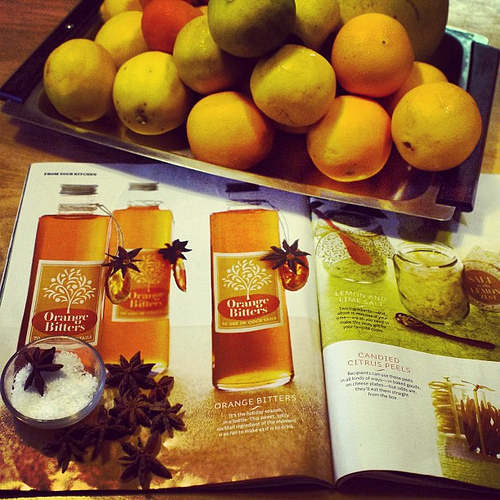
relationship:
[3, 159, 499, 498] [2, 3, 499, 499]
magazine on table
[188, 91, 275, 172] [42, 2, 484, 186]
orange in pile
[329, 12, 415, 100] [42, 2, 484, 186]
orange in pile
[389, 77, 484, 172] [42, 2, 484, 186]
orange in pile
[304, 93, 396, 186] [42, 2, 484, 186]
orange in pile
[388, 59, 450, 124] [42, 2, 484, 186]
orange in pile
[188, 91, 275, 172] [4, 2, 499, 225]
orange on plate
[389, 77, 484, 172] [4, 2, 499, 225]
orange on plate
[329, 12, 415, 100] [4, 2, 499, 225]
orange on plate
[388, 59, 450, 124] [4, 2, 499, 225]
orange on plate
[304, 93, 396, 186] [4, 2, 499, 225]
orange on plate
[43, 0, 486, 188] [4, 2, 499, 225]
fruit on plate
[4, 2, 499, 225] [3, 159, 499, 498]
plate on top of magazine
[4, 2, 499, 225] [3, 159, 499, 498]
plate on magazine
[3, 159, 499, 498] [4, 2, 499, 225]
magazine under plate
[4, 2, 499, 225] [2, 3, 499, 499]
plate on table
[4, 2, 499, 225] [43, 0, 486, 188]
plate contains fruit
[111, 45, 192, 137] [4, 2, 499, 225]
lemon on plate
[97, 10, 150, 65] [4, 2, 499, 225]
lemon on plate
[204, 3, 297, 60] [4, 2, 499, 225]
lime on plate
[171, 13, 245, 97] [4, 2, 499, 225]
lime on plate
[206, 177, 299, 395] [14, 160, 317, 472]
alcohol on image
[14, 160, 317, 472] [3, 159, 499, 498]
image in magazine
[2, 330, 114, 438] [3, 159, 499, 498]
bowl on top of magazine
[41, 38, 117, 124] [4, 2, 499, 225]
fruit on plate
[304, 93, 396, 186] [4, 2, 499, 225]
orange in plate